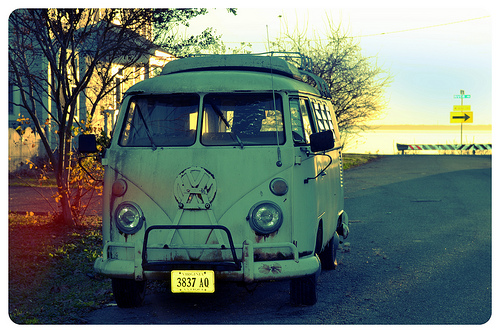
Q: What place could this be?
A: It is a road.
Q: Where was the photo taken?
A: It was taken at the road.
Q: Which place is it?
A: It is a road.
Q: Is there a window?
A: Yes, there are windows.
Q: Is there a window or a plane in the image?
A: Yes, there are windows.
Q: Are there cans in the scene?
A: No, there are no cans.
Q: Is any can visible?
A: No, there are no cans.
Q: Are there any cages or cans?
A: No, there are no cans or cages.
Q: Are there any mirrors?
A: Yes, there is a mirror.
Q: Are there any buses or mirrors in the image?
A: Yes, there is a mirror.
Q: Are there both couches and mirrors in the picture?
A: No, there is a mirror but no couches.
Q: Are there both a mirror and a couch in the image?
A: No, there is a mirror but no couches.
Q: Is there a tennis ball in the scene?
A: No, there are no tennis balls.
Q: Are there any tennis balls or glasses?
A: No, there are no tennis balls or glasses.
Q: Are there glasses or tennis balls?
A: No, there are no tennis balls or glasses.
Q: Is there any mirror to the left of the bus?
A: Yes, there is a mirror to the left of the bus.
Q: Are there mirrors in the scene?
A: Yes, there is a mirror.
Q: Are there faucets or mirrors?
A: Yes, there is a mirror.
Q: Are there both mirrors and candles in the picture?
A: No, there is a mirror but no candles.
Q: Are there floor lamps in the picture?
A: No, there are no floor lamps.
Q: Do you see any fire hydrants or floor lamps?
A: No, there are no floor lamps or fire hydrants.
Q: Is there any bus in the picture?
A: Yes, there is a bus.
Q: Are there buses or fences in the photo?
A: Yes, there is a bus.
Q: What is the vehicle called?
A: The vehicle is a bus.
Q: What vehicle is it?
A: The vehicle is a bus.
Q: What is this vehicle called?
A: This is a bus.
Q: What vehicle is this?
A: This is a bus.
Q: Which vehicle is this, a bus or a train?
A: This is a bus.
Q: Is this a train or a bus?
A: This is a bus.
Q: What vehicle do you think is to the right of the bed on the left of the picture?
A: The vehicle is a bus.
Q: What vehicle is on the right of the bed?
A: The vehicle is a bus.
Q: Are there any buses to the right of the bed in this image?
A: Yes, there is a bus to the right of the bed.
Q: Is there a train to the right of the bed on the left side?
A: No, there is a bus to the right of the bed.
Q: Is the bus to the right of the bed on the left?
A: Yes, the bus is to the right of the bed.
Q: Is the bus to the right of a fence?
A: No, the bus is to the right of the bed.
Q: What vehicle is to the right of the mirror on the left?
A: The vehicle is a bus.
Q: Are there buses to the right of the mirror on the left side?
A: Yes, there is a bus to the right of the mirror.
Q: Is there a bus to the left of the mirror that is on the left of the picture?
A: No, the bus is to the right of the mirror.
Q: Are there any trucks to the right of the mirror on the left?
A: No, there is a bus to the right of the mirror.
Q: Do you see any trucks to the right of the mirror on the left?
A: No, there is a bus to the right of the mirror.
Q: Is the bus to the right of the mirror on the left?
A: Yes, the bus is to the right of the mirror.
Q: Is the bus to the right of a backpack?
A: No, the bus is to the right of the mirror.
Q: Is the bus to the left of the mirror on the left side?
A: No, the bus is to the right of the mirror.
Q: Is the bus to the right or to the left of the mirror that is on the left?
A: The bus is to the right of the mirror.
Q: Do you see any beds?
A: Yes, there is a bed.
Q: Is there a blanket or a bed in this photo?
A: Yes, there is a bed.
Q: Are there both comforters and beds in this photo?
A: No, there is a bed but no comforters.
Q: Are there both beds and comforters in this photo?
A: No, there is a bed but no comforters.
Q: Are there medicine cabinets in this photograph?
A: No, there are no medicine cabinets.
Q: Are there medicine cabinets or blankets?
A: No, there are no medicine cabinets or blankets.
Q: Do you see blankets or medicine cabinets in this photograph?
A: No, there are no medicine cabinets or blankets.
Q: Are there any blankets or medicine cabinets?
A: No, there are no medicine cabinets or blankets.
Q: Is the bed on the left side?
A: Yes, the bed is on the left of the image.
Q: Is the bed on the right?
A: No, the bed is on the left of the image.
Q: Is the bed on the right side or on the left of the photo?
A: The bed is on the left of the image.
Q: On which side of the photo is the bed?
A: The bed is on the left of the image.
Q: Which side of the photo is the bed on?
A: The bed is on the left of the image.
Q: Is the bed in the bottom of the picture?
A: Yes, the bed is in the bottom of the image.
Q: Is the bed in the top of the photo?
A: No, the bed is in the bottom of the image.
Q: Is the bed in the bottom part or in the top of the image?
A: The bed is in the bottom of the image.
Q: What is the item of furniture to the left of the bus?
A: The piece of furniture is a bed.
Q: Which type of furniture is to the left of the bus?
A: The piece of furniture is a bed.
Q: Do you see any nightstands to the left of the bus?
A: No, there is a bed to the left of the bus.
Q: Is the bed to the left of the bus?
A: Yes, the bed is to the left of the bus.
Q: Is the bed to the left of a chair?
A: No, the bed is to the left of the bus.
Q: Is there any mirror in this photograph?
A: Yes, there is a mirror.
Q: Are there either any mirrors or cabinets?
A: Yes, there is a mirror.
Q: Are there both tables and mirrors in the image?
A: No, there is a mirror but no tables.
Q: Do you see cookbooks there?
A: No, there are no cookbooks.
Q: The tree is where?
A: The tree is on the sidewalk.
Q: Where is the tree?
A: The tree is on the sidewalk.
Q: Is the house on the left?
A: Yes, the house is on the left of the image.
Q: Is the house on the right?
A: No, the house is on the left of the image.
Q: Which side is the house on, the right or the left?
A: The house is on the left of the image.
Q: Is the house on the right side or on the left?
A: The house is on the left of the image.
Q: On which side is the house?
A: The house is on the left of the image.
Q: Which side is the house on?
A: The house is on the left of the image.